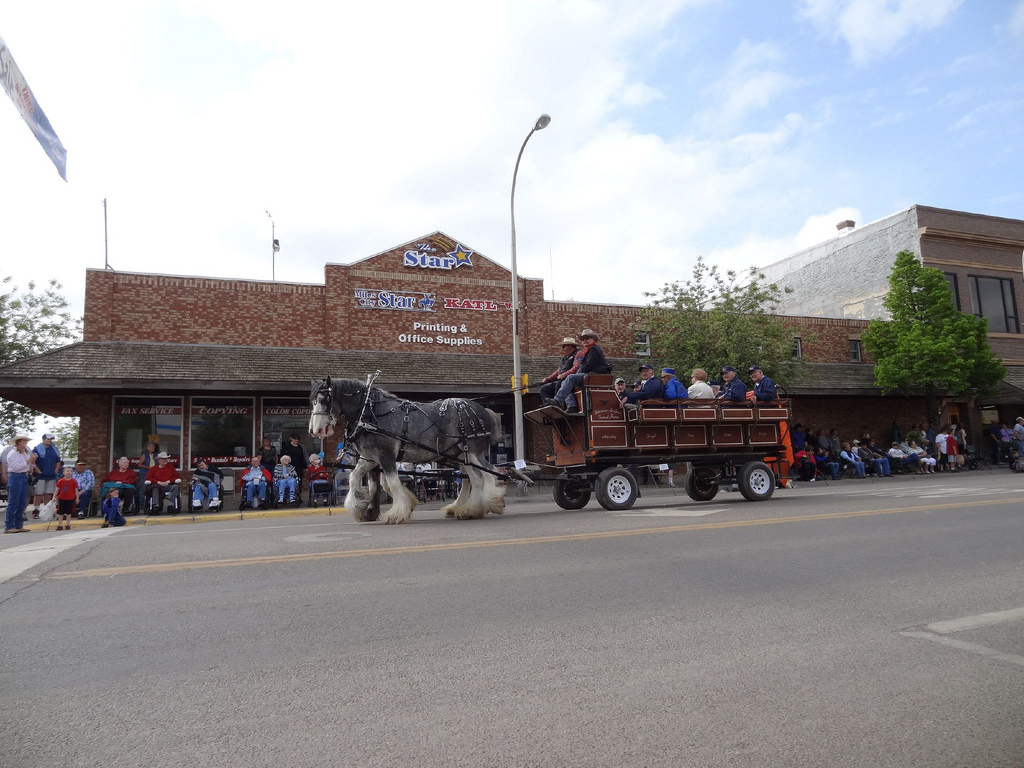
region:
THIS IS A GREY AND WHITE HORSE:
[295, 370, 526, 544]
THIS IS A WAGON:
[520, 375, 792, 516]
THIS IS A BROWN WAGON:
[513, 355, 809, 514]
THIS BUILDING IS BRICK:
[0, 219, 1019, 523]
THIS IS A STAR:
[437, 238, 488, 283]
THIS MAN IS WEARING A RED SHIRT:
[131, 459, 182, 489]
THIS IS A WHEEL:
[585, 457, 642, 511]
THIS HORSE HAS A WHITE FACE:
[302, 388, 344, 449]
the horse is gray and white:
[301, 369, 508, 522]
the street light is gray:
[509, 116, 554, 499]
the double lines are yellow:
[20, 493, 1020, 585]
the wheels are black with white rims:
[552, 456, 775, 510]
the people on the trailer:
[525, 325, 795, 510]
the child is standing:
[52, 462, 78, 530]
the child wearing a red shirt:
[51, 467, 80, 531]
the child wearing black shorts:
[46, 467, 79, 529]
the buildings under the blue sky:
[1, 4, 1020, 505]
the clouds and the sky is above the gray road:
[0, 2, 1021, 767]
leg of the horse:
[462, 473, 501, 515]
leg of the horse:
[450, 495, 463, 530]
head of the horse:
[305, 391, 348, 431]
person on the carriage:
[525, 315, 571, 420]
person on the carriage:
[629, 367, 662, 391]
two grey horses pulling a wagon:
[292, 356, 524, 531]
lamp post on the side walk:
[495, 111, 556, 503]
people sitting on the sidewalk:
[94, 435, 307, 522]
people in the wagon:
[542, 326, 776, 409]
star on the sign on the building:
[448, 234, 474, 273]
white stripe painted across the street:
[12, 511, 114, 587]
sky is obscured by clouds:
[167, 75, 380, 199]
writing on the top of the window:
[115, 397, 188, 426]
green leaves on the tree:
[913, 348, 961, 391]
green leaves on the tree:
[680, 331, 723, 374]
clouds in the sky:
[609, 32, 850, 242]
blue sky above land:
[748, 38, 960, 178]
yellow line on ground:
[174, 521, 330, 623]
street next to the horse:
[391, 571, 613, 695]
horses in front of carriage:
[206, 338, 546, 583]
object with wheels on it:
[482, 331, 846, 548]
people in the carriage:
[493, 310, 823, 466]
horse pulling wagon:
[242, 323, 496, 536]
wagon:
[514, 376, 789, 493]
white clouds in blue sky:
[108, 43, 166, 89]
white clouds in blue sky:
[321, 168, 411, 226]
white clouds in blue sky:
[365, 66, 461, 142]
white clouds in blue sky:
[593, 63, 671, 121]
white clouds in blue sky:
[634, 209, 692, 258]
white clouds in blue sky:
[725, 25, 877, 139]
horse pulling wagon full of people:
[257, 311, 809, 527]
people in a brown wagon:
[510, 294, 805, 517]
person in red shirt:
[99, 446, 144, 529]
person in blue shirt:
[622, 360, 673, 409]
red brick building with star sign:
[8, 209, 936, 478]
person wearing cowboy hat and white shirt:
[7, 427, 39, 541]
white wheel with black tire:
[592, 462, 647, 511]